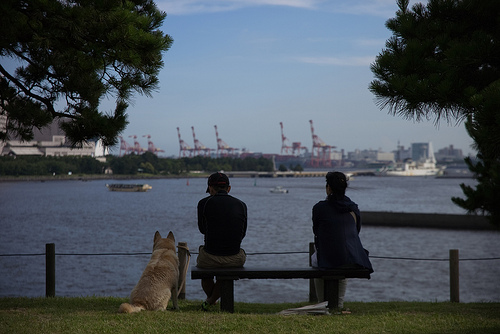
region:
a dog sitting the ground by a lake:
[118, 226, 184, 321]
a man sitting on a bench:
[186, 165, 258, 310]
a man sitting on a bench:
[304, 163, 375, 309]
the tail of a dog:
[117, 299, 147, 316]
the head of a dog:
[146, 226, 181, 253]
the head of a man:
[200, 168, 240, 201]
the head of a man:
[323, 162, 352, 201]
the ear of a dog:
[163, 223, 179, 245]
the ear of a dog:
[151, 225, 163, 240]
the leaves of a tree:
[71, 109, 117, 144]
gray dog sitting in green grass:
[118, 216, 190, 317]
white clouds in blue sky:
[210, 32, 247, 76]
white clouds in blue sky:
[261, 8, 306, 42]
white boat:
[382, 143, 443, 183]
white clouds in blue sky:
[191, 52, 236, 82]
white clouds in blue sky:
[171, 85, 213, 116]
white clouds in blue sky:
[282, 6, 346, 63]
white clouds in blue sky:
[202, 25, 259, 60]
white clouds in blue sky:
[258, 63, 319, 113]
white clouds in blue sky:
[190, 22, 232, 77]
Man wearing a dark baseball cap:
[197, 170, 231, 195]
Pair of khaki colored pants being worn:
[191, 246, 246, 300]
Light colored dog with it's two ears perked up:
[118, 230, 180, 320]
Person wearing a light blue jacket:
[305, 169, 363, 277]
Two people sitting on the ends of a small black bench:
[198, 166, 369, 298]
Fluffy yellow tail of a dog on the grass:
[111, 300, 152, 317]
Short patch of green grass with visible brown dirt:
[22, 303, 109, 327]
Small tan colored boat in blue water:
[103, 176, 157, 198]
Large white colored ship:
[375, 156, 447, 179]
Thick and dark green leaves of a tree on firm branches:
[29, 4, 155, 67]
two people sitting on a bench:
[188, 168, 377, 315]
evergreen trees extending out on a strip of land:
[367, 0, 499, 217]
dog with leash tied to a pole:
[113, 229, 192, 314]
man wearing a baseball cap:
[203, 170, 232, 197]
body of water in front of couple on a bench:
[1, 178, 498, 300]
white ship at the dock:
[383, 158, 441, 177]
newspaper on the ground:
[278, 296, 334, 318]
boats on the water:
[102, 178, 291, 195]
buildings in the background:
[343, 139, 473, 166]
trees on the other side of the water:
[1, 150, 303, 175]